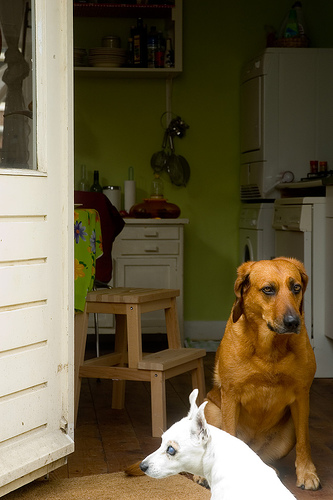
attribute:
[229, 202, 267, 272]
load washer — white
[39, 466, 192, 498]
rug — brown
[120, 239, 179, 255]
drawer — white, wooden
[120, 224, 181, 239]
drawer — white, wooden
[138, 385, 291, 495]
dog — white, colored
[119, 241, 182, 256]
drawer — white